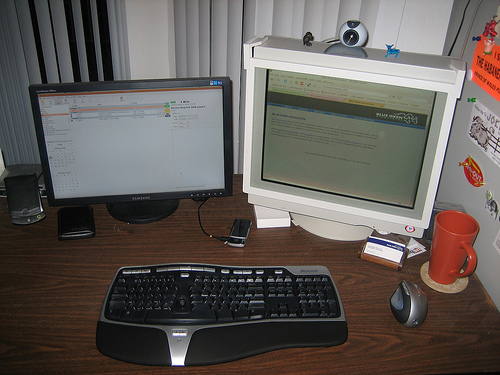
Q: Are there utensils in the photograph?
A: No, there are no utensils.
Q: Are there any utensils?
A: No, there are no utensils.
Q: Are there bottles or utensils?
A: No, there are no utensils or bottles.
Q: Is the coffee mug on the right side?
A: Yes, the coffee mug is on the right of the image.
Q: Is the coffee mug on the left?
A: No, the coffee mug is on the right of the image.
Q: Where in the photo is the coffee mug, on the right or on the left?
A: The coffee mug is on the right of the image.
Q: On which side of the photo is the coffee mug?
A: The coffee mug is on the right of the image.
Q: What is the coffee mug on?
A: The coffee mug is on the desk.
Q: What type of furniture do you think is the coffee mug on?
A: The coffee mug is on the desk.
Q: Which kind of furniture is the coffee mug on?
A: The coffee mug is on the desk.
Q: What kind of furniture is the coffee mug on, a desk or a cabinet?
A: The coffee mug is on a desk.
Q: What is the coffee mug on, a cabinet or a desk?
A: The coffee mug is on a desk.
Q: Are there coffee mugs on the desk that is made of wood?
A: Yes, there is a coffee mug on the desk.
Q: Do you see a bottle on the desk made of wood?
A: No, there is a coffee mug on the desk.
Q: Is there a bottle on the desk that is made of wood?
A: No, there is a coffee mug on the desk.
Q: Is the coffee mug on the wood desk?
A: Yes, the coffee mug is on the desk.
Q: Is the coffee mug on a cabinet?
A: No, the coffee mug is on the desk.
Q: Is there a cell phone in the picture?
A: Yes, there is a cell phone.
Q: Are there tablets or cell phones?
A: Yes, there is a cell phone.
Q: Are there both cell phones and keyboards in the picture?
A: Yes, there are both a cell phone and a keyboard.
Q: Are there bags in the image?
A: No, there are no bags.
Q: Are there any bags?
A: No, there are no bags.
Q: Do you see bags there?
A: No, there are no bags.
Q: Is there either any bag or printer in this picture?
A: No, there are no bags or printers.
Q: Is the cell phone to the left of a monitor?
A: Yes, the cell phone is to the left of a monitor.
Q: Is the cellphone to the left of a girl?
A: No, the cellphone is to the left of a monitor.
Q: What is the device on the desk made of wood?
A: The device is a cell phone.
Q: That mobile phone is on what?
A: The mobile phone is on the desk.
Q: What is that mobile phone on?
A: The mobile phone is on the desk.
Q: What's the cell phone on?
A: The mobile phone is on the desk.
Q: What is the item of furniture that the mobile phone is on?
A: The piece of furniture is a desk.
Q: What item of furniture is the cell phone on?
A: The mobile phone is on the desk.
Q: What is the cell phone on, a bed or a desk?
A: The cell phone is on a desk.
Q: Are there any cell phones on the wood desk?
A: Yes, there is a cell phone on the desk.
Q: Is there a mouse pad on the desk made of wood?
A: No, there is a cell phone on the desk.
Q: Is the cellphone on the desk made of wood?
A: Yes, the cellphone is on the desk.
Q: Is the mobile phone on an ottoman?
A: No, the mobile phone is on the desk.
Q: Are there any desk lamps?
A: No, there are no desk lamps.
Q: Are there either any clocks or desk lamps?
A: No, there are no desk lamps or clocks.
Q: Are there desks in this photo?
A: Yes, there is a desk.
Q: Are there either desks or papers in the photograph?
A: Yes, there is a desk.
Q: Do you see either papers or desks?
A: Yes, there is a desk.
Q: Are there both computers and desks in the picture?
A: Yes, there are both a desk and a computer.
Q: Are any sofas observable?
A: No, there are no sofas.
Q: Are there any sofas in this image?
A: No, there are no sofas.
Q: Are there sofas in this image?
A: No, there are no sofas.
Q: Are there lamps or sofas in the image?
A: No, there are no sofas or lamps.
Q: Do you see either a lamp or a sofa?
A: No, there are no sofas or lamps.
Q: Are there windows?
A: Yes, there is a window.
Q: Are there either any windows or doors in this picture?
A: Yes, there is a window.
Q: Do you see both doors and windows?
A: No, there is a window but no doors.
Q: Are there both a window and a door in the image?
A: No, there is a window but no doors.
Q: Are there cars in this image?
A: No, there are no cars.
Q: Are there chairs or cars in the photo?
A: No, there are no cars or chairs.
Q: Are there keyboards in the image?
A: Yes, there is a keyboard.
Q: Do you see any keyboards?
A: Yes, there is a keyboard.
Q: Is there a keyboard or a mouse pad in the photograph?
A: Yes, there is a keyboard.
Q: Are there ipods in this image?
A: No, there are no ipods.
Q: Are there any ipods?
A: No, there are no ipods.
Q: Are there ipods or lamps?
A: No, there are no ipods or lamps.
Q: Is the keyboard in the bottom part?
A: Yes, the keyboard is in the bottom of the image.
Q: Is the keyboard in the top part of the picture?
A: No, the keyboard is in the bottom of the image.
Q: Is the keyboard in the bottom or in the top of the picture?
A: The keyboard is in the bottom of the image.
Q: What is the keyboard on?
A: The keyboard is on the desk.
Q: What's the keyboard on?
A: The keyboard is on the desk.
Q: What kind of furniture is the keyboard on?
A: The keyboard is on the desk.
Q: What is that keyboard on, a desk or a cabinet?
A: The keyboard is on a desk.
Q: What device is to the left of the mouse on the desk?
A: The device is a keyboard.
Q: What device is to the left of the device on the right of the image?
A: The device is a keyboard.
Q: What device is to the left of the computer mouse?
A: The device is a keyboard.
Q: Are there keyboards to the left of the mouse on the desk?
A: Yes, there is a keyboard to the left of the computer mouse.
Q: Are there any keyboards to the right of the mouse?
A: No, the keyboard is to the left of the mouse.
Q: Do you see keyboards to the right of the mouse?
A: No, the keyboard is to the left of the mouse.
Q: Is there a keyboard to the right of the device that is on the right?
A: No, the keyboard is to the left of the mouse.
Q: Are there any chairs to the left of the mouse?
A: No, there is a keyboard to the left of the mouse.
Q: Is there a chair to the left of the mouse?
A: No, there is a keyboard to the left of the mouse.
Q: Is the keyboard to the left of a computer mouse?
A: Yes, the keyboard is to the left of a computer mouse.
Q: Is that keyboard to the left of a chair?
A: No, the keyboard is to the left of a computer mouse.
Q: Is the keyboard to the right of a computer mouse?
A: No, the keyboard is to the left of a computer mouse.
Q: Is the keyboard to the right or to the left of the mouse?
A: The keyboard is to the left of the mouse.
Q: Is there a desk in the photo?
A: Yes, there is a desk.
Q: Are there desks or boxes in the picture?
A: Yes, there is a desk.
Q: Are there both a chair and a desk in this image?
A: No, there is a desk but no chairs.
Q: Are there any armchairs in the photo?
A: No, there are no armchairs.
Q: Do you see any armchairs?
A: No, there are no armchairs.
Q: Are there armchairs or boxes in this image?
A: No, there are no armchairs or boxes.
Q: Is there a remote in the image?
A: No, there are no remote controls.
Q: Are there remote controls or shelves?
A: No, there are no remote controls or shelves.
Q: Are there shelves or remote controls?
A: No, there are no remote controls or shelves.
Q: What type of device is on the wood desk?
A: The device is a monitor.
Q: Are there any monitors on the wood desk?
A: Yes, there is a monitor on the desk.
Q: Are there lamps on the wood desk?
A: No, there is a monitor on the desk.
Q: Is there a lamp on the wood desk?
A: No, there is a monitor on the desk.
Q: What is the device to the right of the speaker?
A: The device is a monitor.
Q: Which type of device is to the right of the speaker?
A: The device is a monitor.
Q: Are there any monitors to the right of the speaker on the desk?
A: Yes, there is a monitor to the right of the speaker.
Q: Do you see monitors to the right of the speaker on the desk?
A: Yes, there is a monitor to the right of the speaker.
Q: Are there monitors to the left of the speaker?
A: No, the monitor is to the right of the speaker.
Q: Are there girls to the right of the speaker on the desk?
A: No, there is a monitor to the right of the speaker.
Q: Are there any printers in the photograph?
A: No, there are no printers.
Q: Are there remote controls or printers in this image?
A: No, there are no printers or remote controls.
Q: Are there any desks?
A: Yes, there is a desk.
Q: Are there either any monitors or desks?
A: Yes, there is a desk.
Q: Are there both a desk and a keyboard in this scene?
A: Yes, there are both a desk and a keyboard.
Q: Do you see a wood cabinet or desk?
A: Yes, there is a wood desk.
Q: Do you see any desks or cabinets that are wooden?
A: Yes, the desk is wooden.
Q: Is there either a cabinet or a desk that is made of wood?
A: Yes, the desk is made of wood.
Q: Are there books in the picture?
A: No, there are no books.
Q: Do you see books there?
A: No, there are no books.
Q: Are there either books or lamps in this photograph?
A: No, there are no books or lamps.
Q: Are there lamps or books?
A: No, there are no books or lamps.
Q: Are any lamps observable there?
A: No, there are no lamps.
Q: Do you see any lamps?
A: No, there are no lamps.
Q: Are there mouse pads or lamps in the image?
A: No, there are no lamps or mouse pads.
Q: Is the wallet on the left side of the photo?
A: Yes, the wallet is on the left of the image.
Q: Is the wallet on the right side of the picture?
A: No, the wallet is on the left of the image.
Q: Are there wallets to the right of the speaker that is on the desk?
A: Yes, there is a wallet to the right of the speaker.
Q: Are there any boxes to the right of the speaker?
A: No, there is a wallet to the right of the speaker.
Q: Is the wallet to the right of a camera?
A: No, the wallet is to the right of the speaker.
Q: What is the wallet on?
A: The wallet is on the desk.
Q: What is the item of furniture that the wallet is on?
A: The piece of furniture is a desk.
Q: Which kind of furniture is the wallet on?
A: The wallet is on the desk.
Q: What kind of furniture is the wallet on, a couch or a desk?
A: The wallet is on a desk.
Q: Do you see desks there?
A: Yes, there is a desk.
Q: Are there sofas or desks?
A: Yes, there is a desk.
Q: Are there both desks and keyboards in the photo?
A: Yes, there are both a desk and a keyboard.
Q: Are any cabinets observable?
A: No, there are no cabinets.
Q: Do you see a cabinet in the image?
A: No, there are no cabinets.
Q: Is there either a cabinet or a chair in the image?
A: No, there are no cabinets or chairs.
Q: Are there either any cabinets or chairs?
A: No, there are no cabinets or chairs.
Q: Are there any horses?
A: Yes, there is a horse.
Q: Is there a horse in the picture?
A: Yes, there is a horse.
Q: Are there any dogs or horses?
A: Yes, there is a horse.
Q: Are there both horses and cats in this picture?
A: No, there is a horse but no cats.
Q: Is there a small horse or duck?
A: Yes, there is a small horse.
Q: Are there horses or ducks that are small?
A: Yes, the horse is small.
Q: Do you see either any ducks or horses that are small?
A: Yes, the horse is small.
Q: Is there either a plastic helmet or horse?
A: Yes, there is a plastic horse.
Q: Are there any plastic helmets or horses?
A: Yes, there is a plastic horse.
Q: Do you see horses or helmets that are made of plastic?
A: Yes, the horse is made of plastic.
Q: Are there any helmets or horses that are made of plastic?
A: Yes, the horse is made of plastic.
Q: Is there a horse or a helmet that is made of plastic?
A: Yes, the horse is made of plastic.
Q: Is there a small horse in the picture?
A: Yes, there is a small horse.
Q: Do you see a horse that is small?
A: Yes, there is a horse that is small.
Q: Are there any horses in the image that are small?
A: Yes, there is a horse that is small.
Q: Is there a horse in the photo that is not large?
A: Yes, there is a small horse.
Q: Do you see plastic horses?
A: Yes, there is a horse that is made of plastic.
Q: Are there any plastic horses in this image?
A: Yes, there is a horse that is made of plastic.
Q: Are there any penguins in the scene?
A: No, there are no penguins.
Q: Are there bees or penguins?
A: No, there are no penguins or bees.